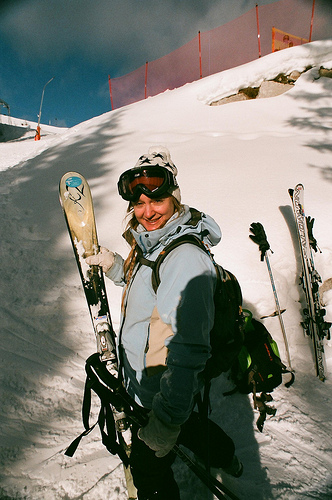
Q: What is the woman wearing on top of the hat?
A: Goggles.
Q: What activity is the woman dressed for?
A: Skiing.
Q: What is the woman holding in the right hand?
A: Skis.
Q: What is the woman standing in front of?
A: A mound of snow.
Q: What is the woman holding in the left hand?
A: Ski poles.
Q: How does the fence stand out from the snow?
A: It is red.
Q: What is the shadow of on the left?
A: A tree.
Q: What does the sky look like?
A: Blue sky with thin clouds.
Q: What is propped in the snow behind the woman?
A: Black and white skis.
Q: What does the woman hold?
A: Snow skis.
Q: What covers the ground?
A: Snow.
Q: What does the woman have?
A: Skis.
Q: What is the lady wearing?
A: A blue top.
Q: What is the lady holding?
A: Poles.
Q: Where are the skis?
A: Lady is holding them.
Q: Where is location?
A: A ski resort.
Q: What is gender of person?
A: Female.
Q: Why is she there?
A: To snow ski.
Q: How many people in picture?
A: One.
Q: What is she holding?
A: Her skis.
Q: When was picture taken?
A: During daylight.